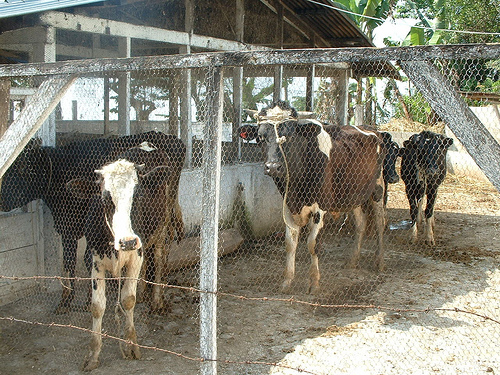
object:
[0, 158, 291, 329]
wall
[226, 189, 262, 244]
green water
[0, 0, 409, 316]
shed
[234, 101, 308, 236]
rope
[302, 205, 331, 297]
leg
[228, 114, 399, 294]
cow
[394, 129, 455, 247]
cow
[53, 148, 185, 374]
cow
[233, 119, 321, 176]
head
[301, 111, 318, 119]
horn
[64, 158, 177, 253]
head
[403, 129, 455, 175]
head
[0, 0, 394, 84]
roof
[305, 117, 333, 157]
spot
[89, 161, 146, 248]
white spot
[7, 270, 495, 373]
wire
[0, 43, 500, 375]
fence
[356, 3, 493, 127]
tree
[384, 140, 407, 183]
head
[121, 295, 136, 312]
knee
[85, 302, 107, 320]
knee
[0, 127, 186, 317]
cow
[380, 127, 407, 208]
cow